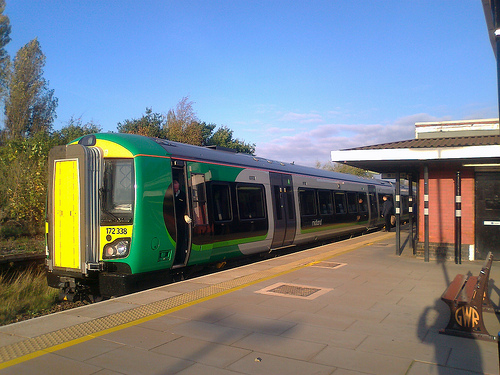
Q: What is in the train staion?
A: A waiting area.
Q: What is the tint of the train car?
A: Green and yellow.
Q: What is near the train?
A: A boarding platform.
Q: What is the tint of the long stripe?
A: Yellow.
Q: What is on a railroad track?
A: Train.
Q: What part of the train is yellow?
A: Front.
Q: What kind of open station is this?
A: Train.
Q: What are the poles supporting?
A: Roof.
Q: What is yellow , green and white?
A: Train.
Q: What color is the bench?
A: Brown.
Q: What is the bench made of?
A: Wood.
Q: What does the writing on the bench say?
A: GWR.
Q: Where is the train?
A: On the tracks.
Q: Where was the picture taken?
A: At a train station.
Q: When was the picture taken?
A: During the day.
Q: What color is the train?
A: Green, yellow, and white.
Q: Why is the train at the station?
A: To pick up passengers.